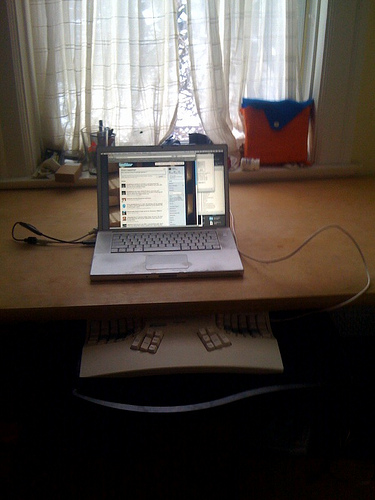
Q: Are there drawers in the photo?
A: No, there are no drawers.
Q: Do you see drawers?
A: No, there are no drawers.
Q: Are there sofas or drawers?
A: No, there are no drawers or sofas.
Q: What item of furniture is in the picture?
A: The piece of furniture is a computer desk.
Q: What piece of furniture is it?
A: The piece of furniture is a computer desk.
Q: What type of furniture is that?
A: This is a computer desk.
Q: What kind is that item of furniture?
A: This is a computer desk.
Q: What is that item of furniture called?
A: This is a computer desk.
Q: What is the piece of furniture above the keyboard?
A: The piece of furniture is a computer desk.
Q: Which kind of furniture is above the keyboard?
A: The piece of furniture is a computer desk.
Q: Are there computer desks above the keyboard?
A: Yes, there is a computer desk above the keyboard.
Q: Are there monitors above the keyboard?
A: No, there is a computer desk above the keyboard.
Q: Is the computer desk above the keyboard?
A: Yes, the computer desk is above the keyboard.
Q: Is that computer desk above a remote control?
A: No, the computer desk is above the keyboard.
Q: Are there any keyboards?
A: Yes, there is a keyboard.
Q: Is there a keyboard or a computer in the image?
A: Yes, there is a keyboard.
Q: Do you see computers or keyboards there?
A: Yes, there is a keyboard.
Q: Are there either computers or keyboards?
A: Yes, there is a keyboard.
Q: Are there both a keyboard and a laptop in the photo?
A: Yes, there are both a keyboard and a laptop.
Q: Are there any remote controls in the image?
A: No, there are no remote controls.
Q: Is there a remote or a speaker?
A: No, there are no remote controls or speakers.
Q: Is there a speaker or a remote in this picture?
A: No, there are no remote controls or speakers.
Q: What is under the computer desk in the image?
A: The keyboard is under the computer desk.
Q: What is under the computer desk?
A: The keyboard is under the computer desk.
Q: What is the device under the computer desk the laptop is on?
A: The device is a keyboard.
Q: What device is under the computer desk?
A: The device is a keyboard.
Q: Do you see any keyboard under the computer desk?
A: Yes, there is a keyboard under the computer desk.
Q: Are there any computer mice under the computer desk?
A: No, there is a keyboard under the computer desk.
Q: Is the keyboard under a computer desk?
A: Yes, the keyboard is under a computer desk.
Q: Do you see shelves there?
A: No, there are no shelves.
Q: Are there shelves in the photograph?
A: No, there are no shelves.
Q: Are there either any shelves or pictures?
A: No, there are no shelves or pictures.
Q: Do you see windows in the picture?
A: Yes, there is a window.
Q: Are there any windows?
A: Yes, there is a window.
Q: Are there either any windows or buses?
A: Yes, there is a window.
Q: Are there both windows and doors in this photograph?
A: No, there is a window but no doors.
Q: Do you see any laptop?
A: Yes, there is a laptop.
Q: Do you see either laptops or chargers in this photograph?
A: Yes, there is a laptop.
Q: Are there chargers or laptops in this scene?
A: Yes, there is a laptop.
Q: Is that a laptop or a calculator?
A: That is a laptop.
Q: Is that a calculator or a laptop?
A: That is a laptop.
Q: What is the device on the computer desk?
A: The device is a laptop.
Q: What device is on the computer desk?
A: The device is a laptop.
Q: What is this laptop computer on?
A: The laptop computer is on the computer desk.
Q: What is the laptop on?
A: The laptop computer is on the computer desk.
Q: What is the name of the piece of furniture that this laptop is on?
A: The piece of furniture is a computer desk.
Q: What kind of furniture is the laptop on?
A: The laptop is on the computer desk.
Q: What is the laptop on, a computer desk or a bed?
A: The laptop is on a computer desk.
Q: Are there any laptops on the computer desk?
A: Yes, there is a laptop on the computer desk.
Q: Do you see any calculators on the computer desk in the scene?
A: No, there is a laptop on the computer desk.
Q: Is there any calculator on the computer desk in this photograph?
A: No, there is a laptop on the computer desk.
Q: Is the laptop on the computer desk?
A: Yes, the laptop is on the computer desk.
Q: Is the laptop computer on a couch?
A: No, the laptop computer is on the computer desk.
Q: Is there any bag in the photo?
A: Yes, there is a bag.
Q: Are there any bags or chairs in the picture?
A: Yes, there is a bag.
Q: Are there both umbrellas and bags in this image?
A: No, there is a bag but no umbrellas.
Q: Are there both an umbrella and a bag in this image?
A: No, there is a bag but no umbrellas.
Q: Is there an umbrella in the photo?
A: No, there are no umbrellas.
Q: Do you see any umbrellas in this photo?
A: No, there are no umbrellas.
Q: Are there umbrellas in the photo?
A: No, there are no umbrellas.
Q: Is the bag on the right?
A: Yes, the bag is on the right of the image.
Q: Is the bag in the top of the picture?
A: Yes, the bag is in the top of the image.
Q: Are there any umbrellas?
A: No, there are no umbrellas.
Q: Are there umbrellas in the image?
A: No, there are no umbrellas.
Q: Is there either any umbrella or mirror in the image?
A: No, there are no umbrellas or mirrors.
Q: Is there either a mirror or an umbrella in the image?
A: No, there are no umbrellas or mirrors.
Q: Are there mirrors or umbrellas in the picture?
A: No, there are no umbrellas or mirrors.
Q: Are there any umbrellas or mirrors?
A: No, there are no umbrellas or mirrors.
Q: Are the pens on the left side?
A: Yes, the pens are on the left of the image.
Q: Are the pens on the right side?
A: No, the pens are on the left of the image.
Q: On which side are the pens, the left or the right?
A: The pens are on the left of the image.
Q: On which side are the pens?
A: The pens are on the left of the image.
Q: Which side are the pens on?
A: The pens are on the left of the image.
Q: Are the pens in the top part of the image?
A: Yes, the pens are in the top of the image.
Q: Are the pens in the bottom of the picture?
A: No, the pens are in the top of the image.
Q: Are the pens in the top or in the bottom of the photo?
A: The pens are in the top of the image.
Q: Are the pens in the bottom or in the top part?
A: The pens are in the top of the image.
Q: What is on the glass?
A: The pens are on the glass.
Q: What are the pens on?
A: The pens are on the glass.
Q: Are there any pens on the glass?
A: Yes, there are pens on the glass.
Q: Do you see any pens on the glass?
A: Yes, there are pens on the glass.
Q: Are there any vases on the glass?
A: No, there are pens on the glass.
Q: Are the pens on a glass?
A: Yes, the pens are on a glass.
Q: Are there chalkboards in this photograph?
A: No, there are no chalkboards.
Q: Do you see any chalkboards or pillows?
A: No, there are no chalkboards or pillows.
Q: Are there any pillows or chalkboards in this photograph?
A: No, there are no chalkboards or pillows.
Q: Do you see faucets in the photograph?
A: No, there are no faucets.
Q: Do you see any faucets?
A: No, there are no faucets.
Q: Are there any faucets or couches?
A: No, there are no faucets or couches.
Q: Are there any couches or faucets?
A: No, there are no faucets or couches.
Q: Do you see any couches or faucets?
A: No, there are no faucets or couches.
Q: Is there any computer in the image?
A: Yes, there is a computer.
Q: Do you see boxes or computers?
A: Yes, there is a computer.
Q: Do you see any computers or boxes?
A: Yes, there is a computer.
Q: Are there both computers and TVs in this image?
A: No, there is a computer but no televisions.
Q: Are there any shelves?
A: No, there are no shelves.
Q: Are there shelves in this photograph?
A: No, there are no shelves.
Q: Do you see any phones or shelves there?
A: No, there are no shelves or phones.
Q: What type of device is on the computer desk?
A: The device is a computer.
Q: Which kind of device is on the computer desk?
A: The device is a computer.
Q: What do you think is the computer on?
A: The computer is on the computer desk.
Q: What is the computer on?
A: The computer is on the computer desk.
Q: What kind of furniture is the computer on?
A: The computer is on the computer desk.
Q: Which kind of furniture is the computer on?
A: The computer is on the computer desk.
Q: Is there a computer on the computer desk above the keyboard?
A: Yes, there is a computer on the computer desk.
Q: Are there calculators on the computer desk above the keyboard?
A: No, there is a computer on the computer desk.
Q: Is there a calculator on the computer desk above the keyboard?
A: No, there is a computer on the computer desk.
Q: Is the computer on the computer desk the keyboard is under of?
A: Yes, the computer is on the computer desk.